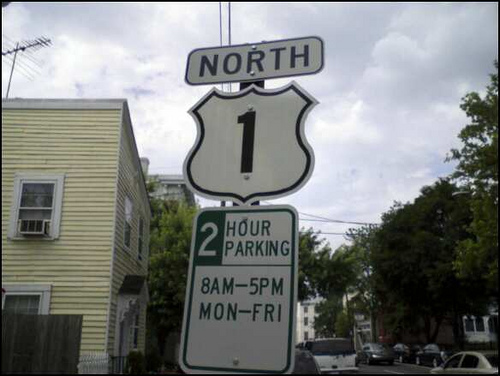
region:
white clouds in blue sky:
[63, 17, 123, 68]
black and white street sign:
[166, 20, 326, 82]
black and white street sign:
[185, 81, 317, 186]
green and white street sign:
[166, 195, 306, 366]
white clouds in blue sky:
[342, 15, 377, 80]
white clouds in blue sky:
[331, 88, 378, 149]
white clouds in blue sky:
[327, 156, 375, 191]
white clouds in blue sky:
[367, 21, 428, 63]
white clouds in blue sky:
[361, 49, 419, 123]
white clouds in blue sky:
[337, 102, 394, 163]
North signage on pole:
[187, 35, 320, 80]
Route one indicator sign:
[179, 80, 315, 209]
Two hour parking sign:
[182, 201, 296, 374]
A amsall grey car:
[355, 337, 394, 369]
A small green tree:
[372, 170, 485, 320]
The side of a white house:
[0, 100, 124, 354]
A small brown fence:
[0, 312, 83, 374]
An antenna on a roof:
[0, 24, 55, 91]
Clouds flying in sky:
[336, 32, 448, 171]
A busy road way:
[295, 314, 499, 374]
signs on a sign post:
[162, 20, 340, 368]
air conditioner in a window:
[7, 213, 69, 247]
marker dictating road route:
[184, 87, 321, 216]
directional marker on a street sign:
[179, 30, 329, 85]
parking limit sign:
[177, 195, 312, 370]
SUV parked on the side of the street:
[295, 330, 366, 374]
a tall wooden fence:
[3, 298, 95, 372]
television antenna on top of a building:
[2, 28, 61, 97]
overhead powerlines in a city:
[300, 205, 387, 236]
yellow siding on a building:
[54, 125, 104, 162]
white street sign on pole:
[175, 31, 329, 81]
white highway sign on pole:
[177, 80, 322, 207]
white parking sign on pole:
[170, 205, 306, 374]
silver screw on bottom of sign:
[229, 357, 243, 372]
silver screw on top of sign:
[234, 213, 254, 225]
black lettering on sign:
[187, 33, 329, 87]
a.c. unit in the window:
[17, 218, 54, 238]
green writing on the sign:
[185, 206, 292, 373]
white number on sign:
[202, 216, 223, 270]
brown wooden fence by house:
[0, 308, 89, 373]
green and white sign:
[184, 200, 306, 374]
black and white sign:
[187, 83, 323, 190]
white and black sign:
[180, 40, 344, 82]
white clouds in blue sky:
[60, 15, 110, 37]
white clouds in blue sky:
[111, 24, 148, 59]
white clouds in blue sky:
[80, 20, 148, 87]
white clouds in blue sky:
[147, 92, 181, 139]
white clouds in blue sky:
[337, 142, 391, 186]